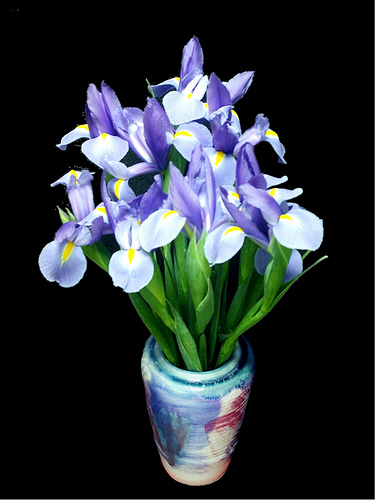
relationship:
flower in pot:
[38, 35, 324, 295] [104, 340, 243, 464]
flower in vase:
[38, 35, 324, 295] [140, 333, 255, 487]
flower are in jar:
[38, 35, 324, 295] [131, 311, 245, 497]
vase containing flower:
[140, 333, 255, 487] [38, 35, 324, 295]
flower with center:
[38, 35, 324, 295] [122, 248, 139, 267]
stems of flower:
[106, 248, 288, 368] [38, 35, 324, 295]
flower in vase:
[38, 35, 324, 295] [138, 328, 264, 488]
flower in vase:
[201, 190, 261, 372] [138, 328, 264, 488]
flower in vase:
[150, 30, 250, 153] [138, 328, 264, 488]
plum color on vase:
[208, 413, 242, 431] [140, 333, 255, 487]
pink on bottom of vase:
[167, 468, 224, 487] [140, 333, 255, 487]